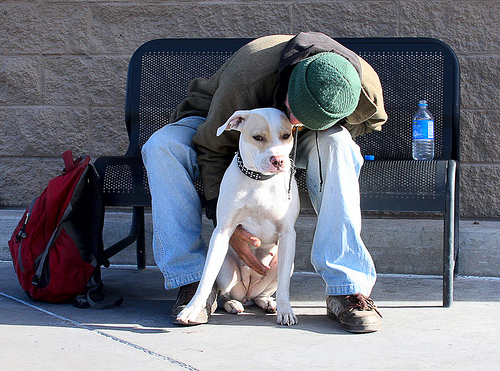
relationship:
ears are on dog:
[211, 101, 324, 156] [223, 88, 312, 356]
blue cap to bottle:
[364, 155, 375, 162] [412, 100, 435, 161]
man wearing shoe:
[137, 30, 388, 337] [324, 294, 381, 334]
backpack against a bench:
[3, 142, 121, 312] [71, 33, 458, 308]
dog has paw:
[175, 107, 300, 327] [173, 300, 227, 325]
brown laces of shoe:
[344, 294, 376, 312] [319, 295, 401, 335]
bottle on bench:
[409, 97, 437, 162] [71, 33, 458, 308]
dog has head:
[175, 107, 300, 327] [221, 96, 298, 182]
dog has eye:
[175, 107, 300, 327] [253, 130, 293, 140]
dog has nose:
[175, 107, 300, 327] [269, 156, 284, 167]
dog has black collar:
[175, 107, 300, 327] [237, 148, 281, 182]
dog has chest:
[175, 107, 300, 327] [246, 183, 286, 250]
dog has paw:
[175, 107, 300, 327] [269, 208, 294, 332]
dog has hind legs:
[175, 103, 300, 338] [208, 252, 290, 327]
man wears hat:
[137, 30, 388, 337] [287, 52, 362, 134]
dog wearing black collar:
[175, 107, 300, 327] [227, 148, 281, 184]